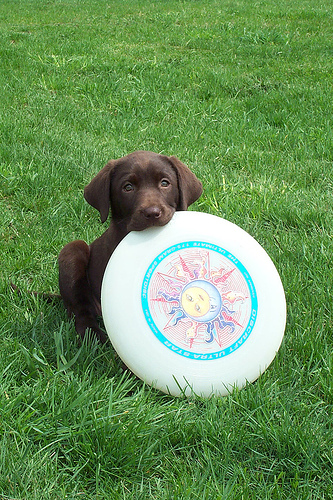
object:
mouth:
[127, 206, 176, 235]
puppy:
[61, 147, 197, 337]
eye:
[119, 180, 136, 193]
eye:
[158, 177, 173, 189]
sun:
[148, 248, 249, 351]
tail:
[9, 281, 62, 304]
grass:
[0, 0, 331, 499]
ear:
[82, 160, 117, 224]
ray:
[178, 253, 194, 281]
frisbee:
[100, 209, 289, 398]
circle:
[140, 239, 258, 360]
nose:
[145, 206, 160, 219]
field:
[2, 0, 333, 500]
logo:
[148, 247, 251, 353]